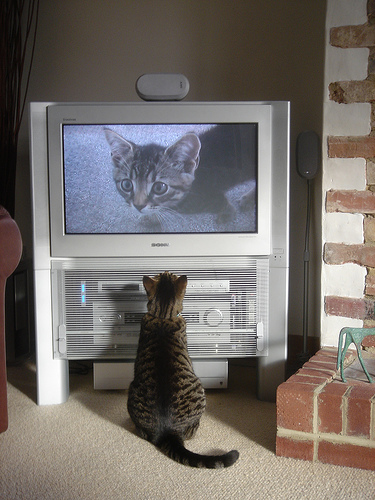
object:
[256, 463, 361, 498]
carpet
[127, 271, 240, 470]
cat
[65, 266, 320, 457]
couch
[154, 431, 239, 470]
cat tail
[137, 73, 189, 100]
speaker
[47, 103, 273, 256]
t.v.